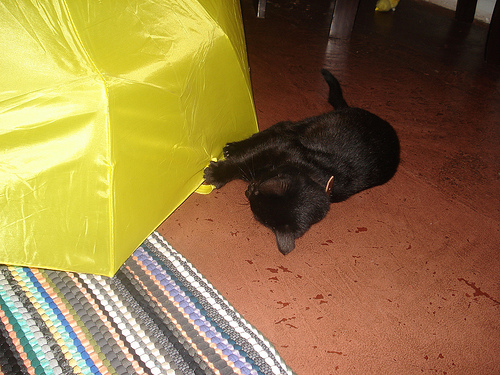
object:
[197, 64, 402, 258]
cat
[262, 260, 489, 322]
floor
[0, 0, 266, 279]
umbrella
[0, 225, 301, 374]
mat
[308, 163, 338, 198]
collar